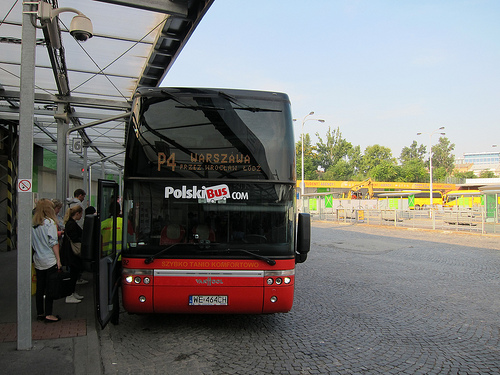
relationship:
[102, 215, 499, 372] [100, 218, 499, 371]
street has cobble stones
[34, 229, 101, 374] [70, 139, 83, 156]
platform in sign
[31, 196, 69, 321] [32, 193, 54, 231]
woman with blonde hair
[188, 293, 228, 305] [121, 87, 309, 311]
license plate on bus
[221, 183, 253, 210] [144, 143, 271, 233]
letters on logo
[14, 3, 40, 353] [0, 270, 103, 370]
pole in concrete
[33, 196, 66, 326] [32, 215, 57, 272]
girl wears white shirt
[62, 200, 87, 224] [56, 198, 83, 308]
hair on woman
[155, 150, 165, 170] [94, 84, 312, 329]
p on bus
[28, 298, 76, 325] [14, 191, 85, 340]
shoes on woman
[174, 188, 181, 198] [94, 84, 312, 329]
o on bus